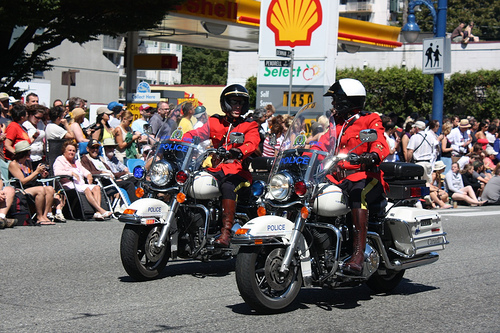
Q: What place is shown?
A: It is a station.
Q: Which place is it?
A: It is a station.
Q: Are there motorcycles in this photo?
A: Yes, there is a motorcycle.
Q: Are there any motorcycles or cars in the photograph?
A: Yes, there is a motorcycle.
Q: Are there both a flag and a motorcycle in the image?
A: No, there is a motorcycle but no flags.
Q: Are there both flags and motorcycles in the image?
A: No, there is a motorcycle but no flags.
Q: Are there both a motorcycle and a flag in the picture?
A: No, there is a motorcycle but no flags.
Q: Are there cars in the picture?
A: No, there are no cars.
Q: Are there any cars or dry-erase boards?
A: No, there are no cars or dry-erase boards.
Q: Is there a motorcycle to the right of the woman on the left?
A: Yes, there is a motorcycle to the right of the woman.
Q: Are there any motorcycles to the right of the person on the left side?
A: Yes, there is a motorcycle to the right of the woman.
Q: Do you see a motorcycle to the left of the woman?
A: No, the motorcycle is to the right of the woman.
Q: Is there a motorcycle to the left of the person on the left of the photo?
A: No, the motorcycle is to the right of the woman.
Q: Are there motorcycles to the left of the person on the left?
A: No, the motorcycle is to the right of the woman.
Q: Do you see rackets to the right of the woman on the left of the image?
A: No, there is a motorcycle to the right of the woman.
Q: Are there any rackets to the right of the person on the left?
A: No, there is a motorcycle to the right of the woman.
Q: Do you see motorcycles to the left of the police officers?
A: Yes, there is a motorcycle to the left of the police officers.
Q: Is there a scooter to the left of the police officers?
A: No, there is a motorcycle to the left of the police officers.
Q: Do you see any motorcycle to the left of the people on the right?
A: Yes, there is a motorcycle to the left of the people.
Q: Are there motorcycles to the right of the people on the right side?
A: No, the motorcycle is to the left of the people.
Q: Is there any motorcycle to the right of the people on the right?
A: No, the motorcycle is to the left of the people.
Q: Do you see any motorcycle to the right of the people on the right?
A: No, the motorcycle is to the left of the people.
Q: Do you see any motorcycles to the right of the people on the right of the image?
A: No, the motorcycle is to the left of the people.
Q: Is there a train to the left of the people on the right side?
A: No, there is a motorcycle to the left of the people.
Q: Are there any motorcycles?
A: Yes, there is a motorcycle.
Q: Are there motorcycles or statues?
A: Yes, there is a motorcycle.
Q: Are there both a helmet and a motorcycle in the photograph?
A: Yes, there are both a motorcycle and a helmet.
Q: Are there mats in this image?
A: No, there are no mats.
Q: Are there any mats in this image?
A: No, there are no mats.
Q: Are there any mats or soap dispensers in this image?
A: No, there are no mats or soap dispensers.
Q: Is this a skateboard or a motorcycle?
A: This is a motorcycle.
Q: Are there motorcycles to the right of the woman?
A: Yes, there is a motorcycle to the right of the woman.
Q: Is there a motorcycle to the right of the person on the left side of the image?
A: Yes, there is a motorcycle to the right of the woman.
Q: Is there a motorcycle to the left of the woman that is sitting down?
A: No, the motorcycle is to the right of the woman.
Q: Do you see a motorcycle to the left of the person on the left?
A: No, the motorcycle is to the right of the woman.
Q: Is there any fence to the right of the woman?
A: No, there is a motorcycle to the right of the woman.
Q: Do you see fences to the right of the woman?
A: No, there is a motorcycle to the right of the woman.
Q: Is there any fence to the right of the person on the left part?
A: No, there is a motorcycle to the right of the woman.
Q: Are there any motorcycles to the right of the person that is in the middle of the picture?
A: Yes, there is a motorcycle to the right of the person.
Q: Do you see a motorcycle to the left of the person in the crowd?
A: No, the motorcycle is to the right of the person.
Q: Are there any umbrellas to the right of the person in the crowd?
A: No, there is a motorcycle to the right of the person.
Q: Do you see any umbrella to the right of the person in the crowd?
A: No, there is a motorcycle to the right of the person.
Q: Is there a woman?
A: Yes, there is a woman.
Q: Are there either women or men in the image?
A: Yes, there is a woman.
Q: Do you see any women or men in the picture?
A: Yes, there is a woman.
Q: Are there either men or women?
A: Yes, there is a woman.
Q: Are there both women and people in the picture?
A: Yes, there are both a woman and a person.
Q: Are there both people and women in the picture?
A: Yes, there are both a woman and a person.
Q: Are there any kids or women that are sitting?
A: Yes, the woman is sitting.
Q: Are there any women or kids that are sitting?
A: Yes, the woman is sitting.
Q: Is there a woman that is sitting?
A: Yes, there is a woman that is sitting.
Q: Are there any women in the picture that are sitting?
A: Yes, there is a woman that is sitting.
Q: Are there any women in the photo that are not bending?
A: Yes, there is a woman that is sitting.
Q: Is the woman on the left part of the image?
A: Yes, the woman is on the left of the image.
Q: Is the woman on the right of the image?
A: No, the woman is on the left of the image.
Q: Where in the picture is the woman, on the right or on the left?
A: The woman is on the left of the image.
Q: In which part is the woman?
A: The woman is on the left of the image.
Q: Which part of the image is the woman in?
A: The woman is on the left of the image.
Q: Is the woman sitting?
A: Yes, the woman is sitting.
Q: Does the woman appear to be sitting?
A: Yes, the woman is sitting.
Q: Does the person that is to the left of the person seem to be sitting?
A: Yes, the woman is sitting.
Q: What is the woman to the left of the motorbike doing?
A: The woman is sitting.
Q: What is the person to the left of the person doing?
A: The woman is sitting.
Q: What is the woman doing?
A: The woman is sitting.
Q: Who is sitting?
A: The woman is sitting.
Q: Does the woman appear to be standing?
A: No, the woman is sitting.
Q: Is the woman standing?
A: No, the woman is sitting.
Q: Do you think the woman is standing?
A: No, the woman is sitting.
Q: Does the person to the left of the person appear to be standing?
A: No, the woman is sitting.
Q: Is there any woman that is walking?
A: No, there is a woman but she is sitting.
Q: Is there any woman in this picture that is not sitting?
A: No, there is a woman but she is sitting.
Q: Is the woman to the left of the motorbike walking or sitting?
A: The woman is sitting.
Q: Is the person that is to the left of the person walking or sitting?
A: The woman is sitting.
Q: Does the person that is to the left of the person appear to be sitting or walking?
A: The woman is sitting.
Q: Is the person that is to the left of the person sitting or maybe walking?
A: The woman is sitting.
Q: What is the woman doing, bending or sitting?
A: The woman is sitting.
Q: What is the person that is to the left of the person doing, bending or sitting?
A: The woman is sitting.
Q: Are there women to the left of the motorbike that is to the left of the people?
A: Yes, there is a woman to the left of the motorcycle.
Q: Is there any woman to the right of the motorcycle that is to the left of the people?
A: No, the woman is to the left of the motorcycle.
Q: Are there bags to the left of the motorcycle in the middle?
A: No, there is a woman to the left of the motorcycle.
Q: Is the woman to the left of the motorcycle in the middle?
A: Yes, the woman is to the left of the motorbike.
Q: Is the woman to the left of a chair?
A: No, the woman is to the left of the motorbike.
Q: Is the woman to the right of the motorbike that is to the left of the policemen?
A: No, the woman is to the left of the motorcycle.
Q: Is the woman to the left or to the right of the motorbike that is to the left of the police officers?
A: The woman is to the left of the motorbike.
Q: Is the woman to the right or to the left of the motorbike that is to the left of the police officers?
A: The woman is to the left of the motorbike.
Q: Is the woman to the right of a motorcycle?
A: No, the woman is to the left of a motorcycle.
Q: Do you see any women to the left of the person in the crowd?
A: Yes, there is a woman to the left of the person.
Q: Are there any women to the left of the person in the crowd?
A: Yes, there is a woman to the left of the person.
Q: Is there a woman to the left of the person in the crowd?
A: Yes, there is a woman to the left of the person.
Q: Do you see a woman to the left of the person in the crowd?
A: Yes, there is a woman to the left of the person.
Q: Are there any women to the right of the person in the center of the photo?
A: No, the woman is to the left of the person.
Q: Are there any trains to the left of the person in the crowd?
A: No, there is a woman to the left of the person.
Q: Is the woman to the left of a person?
A: Yes, the woman is to the left of a person.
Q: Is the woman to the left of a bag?
A: No, the woman is to the left of a person.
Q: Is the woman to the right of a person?
A: No, the woman is to the left of a person.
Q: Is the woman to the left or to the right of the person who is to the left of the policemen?
A: The woman is to the left of the person.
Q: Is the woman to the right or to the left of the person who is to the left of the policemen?
A: The woman is to the left of the person.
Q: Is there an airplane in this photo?
A: No, there are no airplanes.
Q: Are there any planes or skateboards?
A: No, there are no planes or skateboards.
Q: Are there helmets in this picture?
A: Yes, there is a helmet.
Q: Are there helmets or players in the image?
A: Yes, there is a helmet.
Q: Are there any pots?
A: No, there are no pots.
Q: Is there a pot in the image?
A: No, there are no pots.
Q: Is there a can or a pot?
A: No, there are no pots or cans.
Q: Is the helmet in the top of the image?
A: Yes, the helmet is in the top of the image.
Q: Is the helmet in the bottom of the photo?
A: No, the helmet is in the top of the image.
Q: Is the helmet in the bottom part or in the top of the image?
A: The helmet is in the top of the image.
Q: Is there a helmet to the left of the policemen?
A: Yes, there is a helmet to the left of the policemen.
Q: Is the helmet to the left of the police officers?
A: Yes, the helmet is to the left of the police officers.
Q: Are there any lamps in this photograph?
A: Yes, there is a lamp.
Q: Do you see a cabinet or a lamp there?
A: Yes, there is a lamp.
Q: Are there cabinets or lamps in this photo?
A: Yes, there is a lamp.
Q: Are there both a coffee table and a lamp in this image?
A: No, there is a lamp but no coffee tables.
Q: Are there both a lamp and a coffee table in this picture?
A: No, there is a lamp but no coffee tables.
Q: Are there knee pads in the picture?
A: No, there are no knee pads.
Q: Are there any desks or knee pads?
A: No, there are no knee pads or desks.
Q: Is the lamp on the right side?
A: Yes, the lamp is on the right of the image.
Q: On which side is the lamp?
A: The lamp is on the right of the image.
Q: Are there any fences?
A: No, there are no fences.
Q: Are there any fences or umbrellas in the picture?
A: No, there are no fences or umbrellas.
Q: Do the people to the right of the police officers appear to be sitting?
A: Yes, the people are sitting.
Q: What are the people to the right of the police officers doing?
A: The people are sitting.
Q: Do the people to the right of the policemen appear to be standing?
A: No, the people are sitting.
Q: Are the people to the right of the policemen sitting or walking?
A: The people are sitting.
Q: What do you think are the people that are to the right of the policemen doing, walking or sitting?
A: The people are sitting.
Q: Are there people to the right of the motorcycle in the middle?
A: Yes, there are people to the right of the motorbike.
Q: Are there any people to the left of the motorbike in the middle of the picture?
A: No, the people are to the right of the motorbike.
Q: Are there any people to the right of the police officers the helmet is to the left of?
A: Yes, there are people to the right of the police officers.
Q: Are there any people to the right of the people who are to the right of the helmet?
A: Yes, there are people to the right of the police officers.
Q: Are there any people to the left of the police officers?
A: No, the people are to the right of the police officers.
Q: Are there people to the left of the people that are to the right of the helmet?
A: No, the people are to the right of the police officers.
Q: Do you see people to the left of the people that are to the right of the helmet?
A: No, the people are to the right of the police officers.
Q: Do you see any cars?
A: No, there are no cars.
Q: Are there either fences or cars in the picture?
A: No, there are no cars or fences.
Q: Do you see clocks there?
A: No, there are no clocks.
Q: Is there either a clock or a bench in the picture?
A: No, there are no clocks or benches.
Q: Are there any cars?
A: No, there are no cars.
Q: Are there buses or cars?
A: No, there are no cars or buses.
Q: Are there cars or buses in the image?
A: No, there are no cars or buses.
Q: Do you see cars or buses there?
A: No, there are no cars or buses.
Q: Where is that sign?
A: The sign is on the station.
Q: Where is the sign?
A: The sign is on the station.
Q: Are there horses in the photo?
A: No, there are no horses.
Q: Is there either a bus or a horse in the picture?
A: No, there are no horses or buses.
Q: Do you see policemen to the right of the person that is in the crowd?
A: Yes, there are policemen to the right of the person.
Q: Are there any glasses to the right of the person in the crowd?
A: No, there are policemen to the right of the person.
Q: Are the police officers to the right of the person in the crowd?
A: Yes, the police officers are to the right of the person.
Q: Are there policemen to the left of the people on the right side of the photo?
A: Yes, there are policemen to the left of the people.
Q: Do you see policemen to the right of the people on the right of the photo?
A: No, the policemen are to the left of the people.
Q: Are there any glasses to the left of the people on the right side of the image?
A: No, there are policemen to the left of the people.